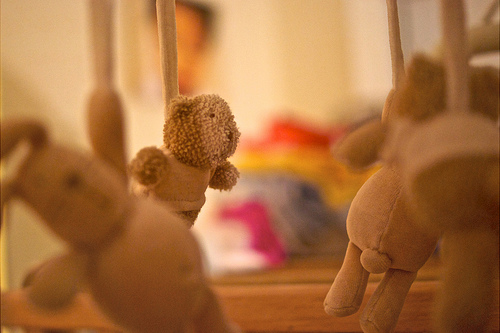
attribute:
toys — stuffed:
[44, 81, 493, 313]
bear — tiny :
[137, 93, 251, 231]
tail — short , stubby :
[354, 246, 394, 273]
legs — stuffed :
[310, 249, 416, 332]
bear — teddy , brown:
[136, 93, 256, 210]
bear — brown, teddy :
[6, 117, 213, 332]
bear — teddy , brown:
[24, 92, 236, 322]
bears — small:
[11, 19, 498, 330]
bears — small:
[13, 10, 232, 330]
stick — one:
[142, 8, 185, 109]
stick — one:
[376, 0, 414, 80]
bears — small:
[327, 51, 498, 324]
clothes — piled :
[219, 107, 362, 278]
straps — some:
[80, 11, 482, 89]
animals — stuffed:
[3, 36, 468, 313]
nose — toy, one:
[55, 164, 84, 191]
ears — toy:
[2, 110, 54, 189]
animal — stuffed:
[325, 44, 462, 331]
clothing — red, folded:
[252, 115, 338, 149]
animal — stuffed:
[322, 54, 492, 329]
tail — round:
[358, 245, 394, 283]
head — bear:
[158, 84, 243, 171]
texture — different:
[165, 84, 237, 177]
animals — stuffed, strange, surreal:
[4, 47, 494, 330]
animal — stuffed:
[117, 80, 254, 223]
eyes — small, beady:
[200, 108, 243, 132]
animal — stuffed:
[312, 51, 470, 322]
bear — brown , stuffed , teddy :
[138, 94, 247, 222]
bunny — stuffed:
[12, 88, 240, 330]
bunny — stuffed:
[308, 42, 474, 331]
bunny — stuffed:
[306, 40, 458, 330]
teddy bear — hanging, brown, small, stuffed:
[128, 93, 240, 226]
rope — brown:
[152, 1, 184, 111]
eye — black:
[208, 110, 217, 120]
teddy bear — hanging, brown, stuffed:
[322, 52, 499, 332]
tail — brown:
[358, 246, 395, 276]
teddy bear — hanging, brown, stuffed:
[128, 90, 246, 232]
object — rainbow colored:
[188, 113, 380, 275]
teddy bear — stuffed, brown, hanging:
[399, 114, 499, 332]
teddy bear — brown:
[0, 85, 234, 331]